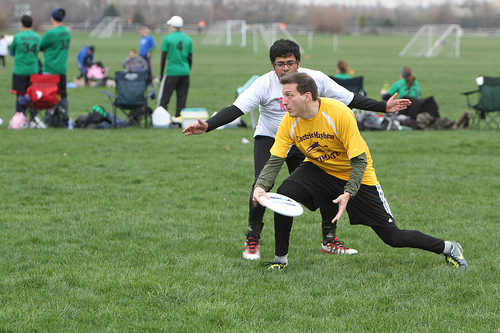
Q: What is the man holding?
A: A frisbee.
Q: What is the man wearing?
A: Shirt and shorts.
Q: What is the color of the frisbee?
A: White.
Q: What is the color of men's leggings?
A: Black.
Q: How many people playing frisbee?
A: Two.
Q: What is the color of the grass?
A: Green.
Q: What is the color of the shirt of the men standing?
A: Green.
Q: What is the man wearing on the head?
A: Eyeglasses.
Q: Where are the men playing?
A: On the field.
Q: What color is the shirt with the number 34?
A: Green.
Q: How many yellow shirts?
A: 1.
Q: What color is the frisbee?
A: White.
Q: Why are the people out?
A: They are playing frisbee.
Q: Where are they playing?
A: On a big field.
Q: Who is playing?
A: Men and boys.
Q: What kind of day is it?
A: It is cloudy.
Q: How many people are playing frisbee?
A: 2 people.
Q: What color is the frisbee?
A: The frisbee is white.